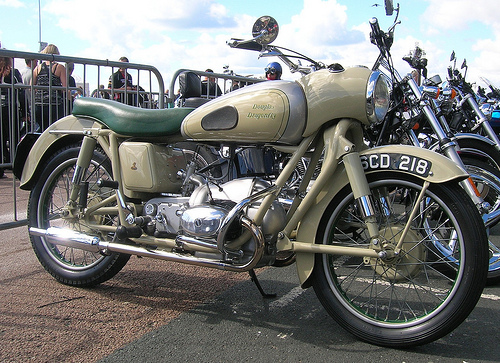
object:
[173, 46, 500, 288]
motorcycle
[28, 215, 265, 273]
muffler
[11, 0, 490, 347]
motorcycle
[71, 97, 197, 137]
green seat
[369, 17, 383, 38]
handlebar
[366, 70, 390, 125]
headlight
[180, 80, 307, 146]
tank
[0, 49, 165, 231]
barrier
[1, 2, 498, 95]
sky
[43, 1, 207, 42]
cloud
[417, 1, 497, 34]
cloud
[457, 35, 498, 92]
cloud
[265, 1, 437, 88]
cloud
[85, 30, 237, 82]
cloud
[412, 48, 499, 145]
motorcycle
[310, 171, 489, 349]
tire